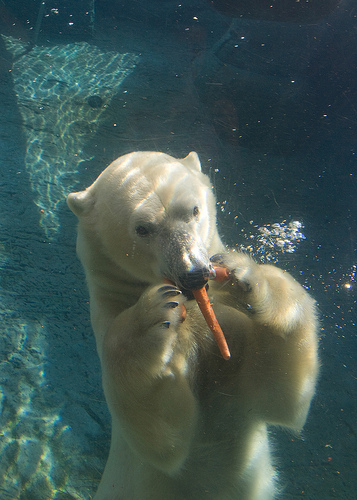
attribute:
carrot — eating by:
[183, 284, 237, 358]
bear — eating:
[63, 146, 321, 498]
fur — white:
[124, 176, 149, 197]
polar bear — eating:
[67, 150, 322, 497]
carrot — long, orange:
[169, 272, 242, 365]